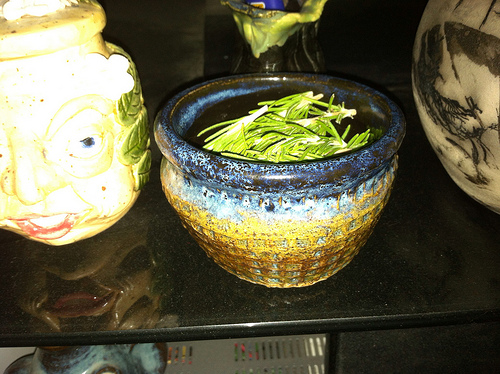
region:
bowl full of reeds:
[153, 68, 408, 297]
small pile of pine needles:
[191, 80, 378, 165]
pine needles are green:
[183, 91, 378, 163]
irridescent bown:
[154, 66, 419, 296]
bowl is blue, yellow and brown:
[148, 63, 407, 299]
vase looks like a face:
[0, 2, 152, 253]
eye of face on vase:
[49, 105, 119, 179]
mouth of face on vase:
[9, 214, 82, 247]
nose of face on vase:
[6, 125, 58, 206]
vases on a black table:
[3, 3, 499, 348]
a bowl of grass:
[100, 56, 464, 287]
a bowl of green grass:
[132, 54, 459, 340]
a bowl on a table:
[189, 43, 495, 299]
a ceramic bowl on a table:
[135, 57, 456, 318]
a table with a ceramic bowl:
[134, 48, 472, 323]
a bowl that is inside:
[123, 23, 433, 283]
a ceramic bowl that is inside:
[182, 30, 494, 296]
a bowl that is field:
[141, 48, 497, 362]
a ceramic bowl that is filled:
[162, 48, 428, 270]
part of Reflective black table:
[1, 296, 52, 333]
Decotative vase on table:
[157, 45, 438, 302]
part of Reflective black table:
[405, 260, 453, 302]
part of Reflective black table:
[420, 197, 453, 228]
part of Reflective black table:
[152, 234, 196, 266]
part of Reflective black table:
[205, 260, 296, 308]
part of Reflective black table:
[283, 283, 417, 317]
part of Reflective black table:
[369, 235, 481, 292]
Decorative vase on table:
[0, 6, 151, 306]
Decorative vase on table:
[400, 7, 495, 219]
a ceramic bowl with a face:
[0, 0, 175, 258]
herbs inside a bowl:
[194, 74, 383, 174]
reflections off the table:
[24, 204, 164, 331]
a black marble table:
[4, 148, 498, 345]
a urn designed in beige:
[404, 0, 498, 220]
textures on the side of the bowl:
[151, 54, 398, 295]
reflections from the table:
[221, 2, 343, 72]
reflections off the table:
[227, 279, 344, 321]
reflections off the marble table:
[401, 209, 498, 306]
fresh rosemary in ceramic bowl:
[197, 87, 374, 166]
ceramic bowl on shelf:
[146, 65, 413, 297]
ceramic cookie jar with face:
[2, 0, 155, 256]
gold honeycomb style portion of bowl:
[156, 163, 418, 293]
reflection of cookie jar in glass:
[2, 210, 187, 342]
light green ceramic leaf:
[219, 2, 337, 59]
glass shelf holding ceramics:
[1, 82, 498, 353]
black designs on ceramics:
[406, 0, 498, 211]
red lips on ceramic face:
[6, 210, 91, 240]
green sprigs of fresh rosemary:
[190, 88, 376, 165]